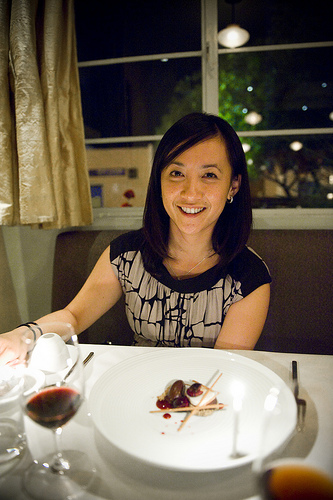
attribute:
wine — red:
[23, 387, 80, 427]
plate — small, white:
[90, 347, 299, 473]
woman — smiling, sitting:
[2, 111, 270, 351]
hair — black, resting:
[142, 111, 252, 266]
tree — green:
[157, 52, 273, 179]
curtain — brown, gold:
[2, 0, 93, 229]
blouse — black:
[108, 231, 271, 348]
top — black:
[106, 227, 272, 346]